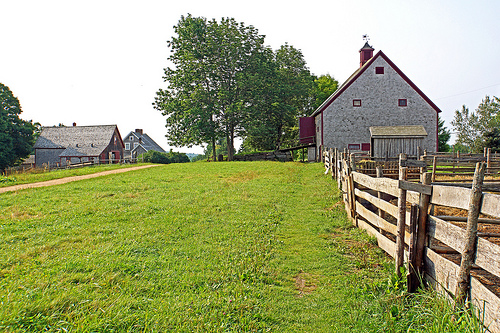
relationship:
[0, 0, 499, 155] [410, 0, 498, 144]
clouds in sky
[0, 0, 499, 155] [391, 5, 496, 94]
clouds in blue sky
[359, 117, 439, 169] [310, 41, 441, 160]
shed behind barn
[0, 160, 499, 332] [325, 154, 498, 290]
grass near a fence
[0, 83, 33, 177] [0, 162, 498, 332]
tree in farm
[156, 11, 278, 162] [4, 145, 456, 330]
tree in field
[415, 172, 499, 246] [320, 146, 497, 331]
hay inside of fence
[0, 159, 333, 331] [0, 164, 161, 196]
grass with pathway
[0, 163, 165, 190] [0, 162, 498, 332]
pathway running through farm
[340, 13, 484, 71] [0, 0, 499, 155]
clouds in blue sky